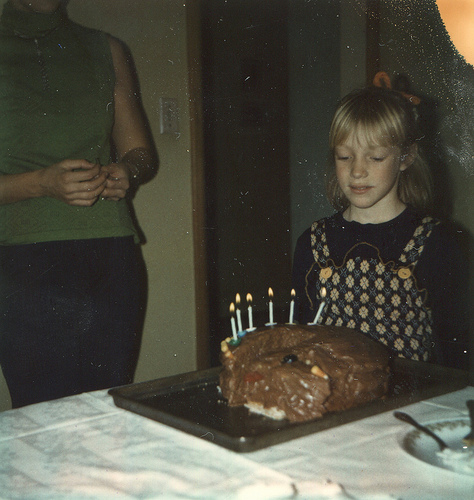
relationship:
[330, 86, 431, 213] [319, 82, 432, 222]
blonde hair on girl's head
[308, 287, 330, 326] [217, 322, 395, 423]
candle on cake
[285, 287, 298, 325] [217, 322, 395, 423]
candle on cake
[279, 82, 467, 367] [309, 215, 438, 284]
girl wearing suspenders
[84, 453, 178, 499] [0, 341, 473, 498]
tablecloth on table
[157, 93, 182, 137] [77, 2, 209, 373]
light switch on wall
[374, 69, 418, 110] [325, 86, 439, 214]
ribbon in blonde hair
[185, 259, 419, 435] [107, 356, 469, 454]
cake on pan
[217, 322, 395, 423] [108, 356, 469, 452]
cake on tray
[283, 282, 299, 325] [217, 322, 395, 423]
candle on cake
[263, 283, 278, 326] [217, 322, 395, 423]
candle on cake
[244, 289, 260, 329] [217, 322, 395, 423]
candle on cake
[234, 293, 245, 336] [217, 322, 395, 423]
candle on cake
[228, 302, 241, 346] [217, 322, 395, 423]
candle on cake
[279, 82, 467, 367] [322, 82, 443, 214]
girl has hair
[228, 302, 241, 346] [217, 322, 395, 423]
candle over cake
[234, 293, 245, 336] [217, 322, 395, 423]
candle over cake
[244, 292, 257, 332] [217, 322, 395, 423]
candle over cake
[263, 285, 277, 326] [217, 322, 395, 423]
candle over cake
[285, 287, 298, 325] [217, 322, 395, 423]
candle over cake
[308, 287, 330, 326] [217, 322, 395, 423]
candle over cake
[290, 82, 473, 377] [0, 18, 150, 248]
girl wearing shirt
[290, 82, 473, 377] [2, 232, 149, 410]
girl wearing jeans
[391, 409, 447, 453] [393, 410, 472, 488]
fork in dish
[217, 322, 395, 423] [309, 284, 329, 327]
cake has candle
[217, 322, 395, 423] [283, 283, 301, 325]
cake has candle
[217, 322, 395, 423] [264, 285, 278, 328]
cake has candle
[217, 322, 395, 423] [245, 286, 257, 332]
cake has candle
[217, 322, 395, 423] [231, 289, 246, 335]
cake has candle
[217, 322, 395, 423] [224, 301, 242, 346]
cake has candle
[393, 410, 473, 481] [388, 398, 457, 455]
dish has spoon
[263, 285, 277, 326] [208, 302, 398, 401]
candle on cake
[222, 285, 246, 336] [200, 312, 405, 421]
candle on cake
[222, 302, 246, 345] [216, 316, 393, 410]
candle on cake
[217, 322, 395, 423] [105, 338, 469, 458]
cake on pan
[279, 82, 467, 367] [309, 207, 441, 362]
girl wearing dress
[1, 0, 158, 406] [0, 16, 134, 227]
woman wearing shirt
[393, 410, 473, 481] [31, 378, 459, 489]
dish on table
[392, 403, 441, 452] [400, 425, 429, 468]
fork on plate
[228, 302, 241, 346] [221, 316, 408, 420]
candle on cake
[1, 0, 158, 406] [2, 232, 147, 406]
woman wearing jeans